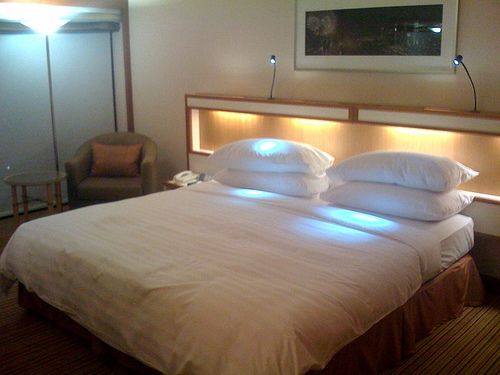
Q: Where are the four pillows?
A: On the bed.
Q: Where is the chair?
A: In the corner.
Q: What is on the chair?
A: A pillow.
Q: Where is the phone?
A: On the nightstand to the left of the bed.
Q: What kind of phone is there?
A: White landline.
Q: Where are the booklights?
A: Above the headboard.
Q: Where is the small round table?
A: To the left of the chaiar.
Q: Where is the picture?
A: Over the bed.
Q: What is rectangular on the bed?
A: Pillows.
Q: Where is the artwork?
A: Above bed.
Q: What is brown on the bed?
A: Bed skirt.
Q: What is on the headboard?
A: Lights.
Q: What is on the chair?
A: Pillow.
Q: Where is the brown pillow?
A: On chair.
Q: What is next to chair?
A: Table.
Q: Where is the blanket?
A: On bed.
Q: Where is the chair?
A: In the corner.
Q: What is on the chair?
A: Pillow.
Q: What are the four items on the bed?
A: Pillows.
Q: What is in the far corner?
A: Chair.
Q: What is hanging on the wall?
A: A picture.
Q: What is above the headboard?
A: A picture.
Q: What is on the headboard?
A: Lights.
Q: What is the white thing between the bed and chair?
A: Telephone.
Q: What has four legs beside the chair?
A: Side table.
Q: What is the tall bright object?
A: Floor lamp.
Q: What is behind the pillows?
A: Headboard.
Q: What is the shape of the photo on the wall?
A: Rectangle.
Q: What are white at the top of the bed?
A: Pillows.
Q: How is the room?
A: Neat.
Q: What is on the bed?
A: Pillows.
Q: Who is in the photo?
A: No one.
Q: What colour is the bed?
A: White.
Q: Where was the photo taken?
A: In a bedroom.